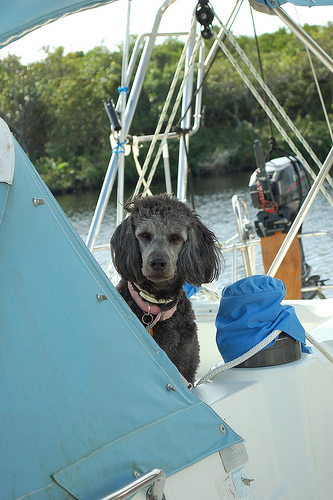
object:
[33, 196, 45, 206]
attachment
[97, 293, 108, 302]
attachment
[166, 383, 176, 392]
attachment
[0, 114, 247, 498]
canvas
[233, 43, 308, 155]
ropes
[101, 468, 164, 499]
handle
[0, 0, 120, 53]
awning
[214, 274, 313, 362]
tarp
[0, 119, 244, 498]
tarp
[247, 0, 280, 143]
rope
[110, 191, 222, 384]
dog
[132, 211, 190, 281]
dog's face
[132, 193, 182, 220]
hair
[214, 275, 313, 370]
robe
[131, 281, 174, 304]
collar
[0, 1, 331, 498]
cover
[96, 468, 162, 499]
hand railing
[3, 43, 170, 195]
tree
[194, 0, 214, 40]
pulley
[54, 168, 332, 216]
shore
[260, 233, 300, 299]
board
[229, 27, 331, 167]
green trees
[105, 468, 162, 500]
railing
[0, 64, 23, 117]
greenery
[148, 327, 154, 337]
tag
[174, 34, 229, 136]
rope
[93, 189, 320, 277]
water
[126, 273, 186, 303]
neck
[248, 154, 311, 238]
motor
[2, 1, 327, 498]
boat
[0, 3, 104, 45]
trim